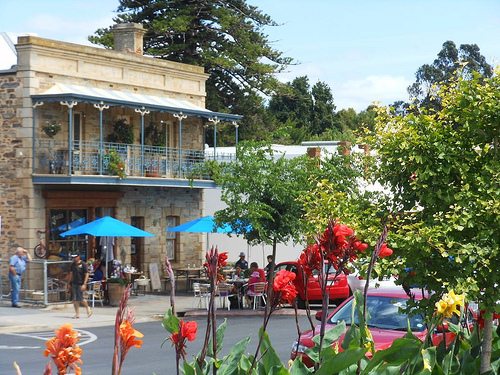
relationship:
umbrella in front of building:
[80, 209, 143, 250] [80, 74, 212, 181]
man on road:
[62, 252, 98, 306] [187, 328, 251, 356]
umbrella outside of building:
[80, 209, 143, 250] [0, 22, 206, 304]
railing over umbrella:
[35, 138, 242, 178] [80, 209, 143, 250]